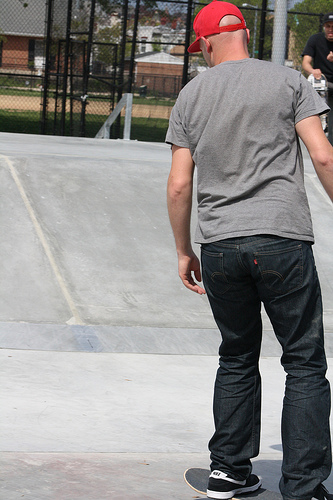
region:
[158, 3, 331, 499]
a man skateboarding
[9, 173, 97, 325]
a line in the concrete wall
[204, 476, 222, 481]
company logo on a sneaker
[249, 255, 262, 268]
a red tag on his pants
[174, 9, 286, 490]
a man wearing a gray t-shirt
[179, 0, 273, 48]
a red hat on a head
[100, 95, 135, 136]
a metal railing on the steps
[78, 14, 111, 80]
a black mesh fence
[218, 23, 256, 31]
a red fastener on a hat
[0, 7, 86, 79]
a brick house on the other side of the fence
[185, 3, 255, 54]
Red ballcap on bald head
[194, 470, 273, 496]
Black tennis shoes with white trim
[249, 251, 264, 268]
Red tag on back pocket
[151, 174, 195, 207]
Elbow on left arm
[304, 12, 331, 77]
Man in a black shirt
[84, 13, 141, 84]
Black fence at skate park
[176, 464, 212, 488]
Top of gray skateboard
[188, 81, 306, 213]
Gray tshirt on man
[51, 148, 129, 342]
Cement slope in park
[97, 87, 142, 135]
Hand rail for steps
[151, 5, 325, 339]
young man on skateboard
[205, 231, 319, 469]
skateboarder's levi blue jeans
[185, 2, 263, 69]
red cap on skateboarder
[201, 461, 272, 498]
black and white sneakers on skateboarder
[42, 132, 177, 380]
ramp at skateboard park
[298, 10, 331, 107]
skateboarder on top of ramp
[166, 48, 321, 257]
gray short sleeved tee shirt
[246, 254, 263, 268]
red tag on levi jeans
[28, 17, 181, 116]
chain link fence at skateboard park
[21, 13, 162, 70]
houses behind skateboard park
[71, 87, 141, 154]
A metal handrail.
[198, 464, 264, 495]
The man is wearing black and white shoes.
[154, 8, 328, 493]
The man is skateboarding.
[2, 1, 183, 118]
Houses in the background.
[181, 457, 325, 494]
The top of the skateboard has grip tape on it.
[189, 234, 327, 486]
The man is wearing jeans.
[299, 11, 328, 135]
The man is watching the skateboarder.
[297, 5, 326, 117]
The man is holding a skateboard.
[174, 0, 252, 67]
The man is wearing a red hat.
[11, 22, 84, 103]
A black chain-link fence.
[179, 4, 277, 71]
Red hat on man's head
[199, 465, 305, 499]
Man is wearing black Nike tennis shoes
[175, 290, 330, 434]
Man is wearing blue jeans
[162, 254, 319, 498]
Man is skateboarding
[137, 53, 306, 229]
Man is wearing gray t-shirt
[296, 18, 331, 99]
Man in black watching skateboarder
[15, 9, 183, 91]
Black metal fence in the background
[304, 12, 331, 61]
Man wearing a black hat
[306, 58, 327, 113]
Man is holding a skateboard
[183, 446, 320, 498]
Man is standing on a skateboard